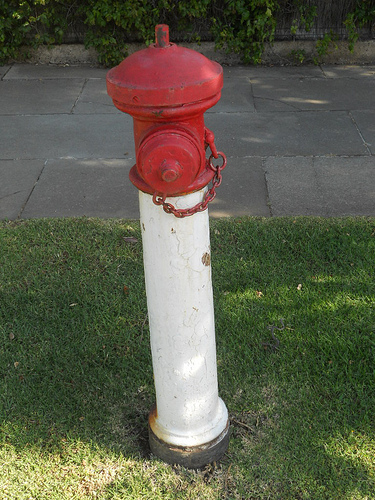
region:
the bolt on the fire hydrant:
[151, 20, 174, 50]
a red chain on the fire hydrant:
[152, 148, 238, 219]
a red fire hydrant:
[98, 19, 243, 218]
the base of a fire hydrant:
[129, 185, 234, 466]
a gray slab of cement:
[259, 152, 374, 218]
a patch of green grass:
[1, 217, 373, 498]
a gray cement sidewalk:
[1, 61, 373, 221]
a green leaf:
[262, 7, 274, 18]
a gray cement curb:
[5, 40, 374, 66]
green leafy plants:
[0, 0, 371, 64]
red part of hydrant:
[109, 21, 229, 197]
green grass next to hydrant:
[32, 392, 111, 463]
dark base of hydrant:
[148, 422, 251, 498]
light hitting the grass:
[31, 432, 118, 497]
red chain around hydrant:
[136, 162, 240, 252]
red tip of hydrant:
[146, 16, 177, 52]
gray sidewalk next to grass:
[254, 79, 344, 193]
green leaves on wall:
[229, 4, 284, 60]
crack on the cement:
[55, 69, 99, 132]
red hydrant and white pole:
[95, 17, 251, 255]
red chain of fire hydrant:
[135, 128, 244, 237]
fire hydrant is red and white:
[100, 23, 254, 346]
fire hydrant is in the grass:
[105, 380, 361, 498]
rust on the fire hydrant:
[118, 387, 173, 456]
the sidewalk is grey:
[253, 102, 357, 212]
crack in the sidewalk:
[244, 83, 312, 123]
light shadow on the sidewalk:
[246, 66, 341, 116]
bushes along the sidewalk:
[13, 11, 373, 66]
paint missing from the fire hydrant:
[192, 234, 222, 281]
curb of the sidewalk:
[19, 44, 104, 77]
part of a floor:
[270, 124, 324, 184]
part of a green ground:
[273, 400, 326, 457]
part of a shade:
[255, 395, 315, 464]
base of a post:
[190, 452, 217, 463]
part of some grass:
[283, 435, 321, 479]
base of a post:
[181, 440, 228, 465]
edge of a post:
[186, 390, 220, 451]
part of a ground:
[290, 406, 325, 453]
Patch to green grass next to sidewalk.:
[5, 221, 127, 428]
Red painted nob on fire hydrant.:
[137, 127, 206, 196]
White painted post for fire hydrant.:
[136, 192, 230, 447]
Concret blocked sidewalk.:
[227, 62, 373, 214]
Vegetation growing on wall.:
[1, 0, 117, 68]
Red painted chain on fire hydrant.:
[145, 150, 226, 217]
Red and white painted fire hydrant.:
[107, 24, 232, 457]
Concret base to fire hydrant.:
[147, 429, 230, 469]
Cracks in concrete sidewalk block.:
[245, 81, 305, 113]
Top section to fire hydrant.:
[105, 24, 222, 119]